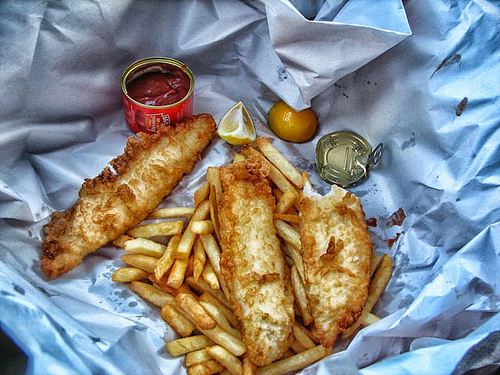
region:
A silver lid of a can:
[312, 127, 387, 188]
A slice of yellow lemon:
[214, 100, 260, 147]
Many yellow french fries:
[105, 159, 394, 373]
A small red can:
[119, 53, 197, 137]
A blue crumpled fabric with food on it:
[0, 0, 499, 372]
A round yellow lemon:
[265, 96, 323, 144]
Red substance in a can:
[120, 53, 199, 137]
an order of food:
[19, 8, 485, 371]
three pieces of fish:
[46, 108, 385, 370]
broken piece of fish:
[272, 125, 431, 374]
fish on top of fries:
[88, 119, 418, 367]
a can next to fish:
[83, 22, 212, 137]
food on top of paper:
[2, 3, 492, 373]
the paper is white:
[0, 9, 488, 369]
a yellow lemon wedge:
[248, 80, 351, 187]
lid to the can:
[302, 118, 397, 200]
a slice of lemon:
[208, 86, 279, 171]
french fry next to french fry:
[173, 198, 205, 255]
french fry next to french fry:
[196, 322, 247, 354]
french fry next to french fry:
[188, 217, 213, 232]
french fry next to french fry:
[145, 206, 196, 214]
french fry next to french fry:
[126, 218, 182, 235]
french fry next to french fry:
[122, 236, 164, 256]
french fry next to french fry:
[122, 255, 157, 272]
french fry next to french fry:
[110, 268, 148, 283]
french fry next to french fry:
[166, 256, 186, 286]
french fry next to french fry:
[162, 303, 196, 337]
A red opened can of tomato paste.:
[118, 58, 193, 134]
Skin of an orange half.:
[268, 102, 319, 144]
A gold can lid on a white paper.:
[316, 129, 383, 186]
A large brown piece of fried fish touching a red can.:
[39, 113, 219, 278]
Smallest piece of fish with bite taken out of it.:
[300, 177, 372, 352]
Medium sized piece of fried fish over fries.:
[219, 155, 296, 366]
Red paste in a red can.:
[127, 71, 189, 106]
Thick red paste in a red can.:
[129, 72, 191, 106]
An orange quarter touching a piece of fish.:
[218, 99, 255, 144]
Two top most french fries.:
[240, 135, 304, 195]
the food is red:
[123, 63, 191, 103]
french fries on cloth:
[138, 188, 278, 367]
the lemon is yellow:
[266, 94, 318, 134]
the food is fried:
[74, 113, 394, 352]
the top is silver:
[317, 126, 405, 181]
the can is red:
[119, 56, 201, 127]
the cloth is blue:
[12, 20, 488, 372]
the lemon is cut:
[217, 93, 262, 147]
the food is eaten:
[301, 166, 381, 355]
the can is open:
[125, 51, 196, 126]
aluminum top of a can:
[313, 128, 383, 185]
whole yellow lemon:
[265, 97, 317, 147]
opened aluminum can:
[120, 55, 195, 137]